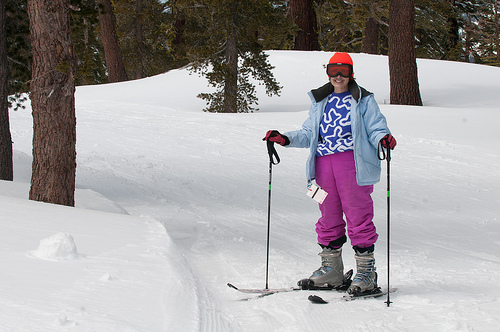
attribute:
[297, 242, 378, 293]
boots — tall, grey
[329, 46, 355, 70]
cap — orange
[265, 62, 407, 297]
woman — standing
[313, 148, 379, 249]
pants — purple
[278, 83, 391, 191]
jacket — blue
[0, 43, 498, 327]
snow — white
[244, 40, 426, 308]
woman — skiing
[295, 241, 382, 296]
boots — gray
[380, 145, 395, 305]
pole —  black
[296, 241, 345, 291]
ski boot — gray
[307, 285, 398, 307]
ski — black, grey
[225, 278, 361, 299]
ski — grey, black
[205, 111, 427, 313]
poles — long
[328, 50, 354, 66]
hat — bright orange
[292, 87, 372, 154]
sweater — blue, white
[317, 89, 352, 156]
sweater — dark blue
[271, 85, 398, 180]
jacket —  light blue, black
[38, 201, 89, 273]
snow — powdery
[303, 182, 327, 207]
tag — black, white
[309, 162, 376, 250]
pants — bright pink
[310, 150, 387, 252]
pants —  purple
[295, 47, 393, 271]
skier — skiing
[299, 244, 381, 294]
ski shoes —  grey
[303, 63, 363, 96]
goggles — black, red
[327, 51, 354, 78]
hat — orange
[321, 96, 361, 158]
shirt — blue, white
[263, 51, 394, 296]
woman — smiling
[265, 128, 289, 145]
glove — red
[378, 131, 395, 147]
glove — red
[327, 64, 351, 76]
goggles — big, black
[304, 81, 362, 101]
collar — light blue, black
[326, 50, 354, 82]
hat — orange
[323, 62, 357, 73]
goggles — clear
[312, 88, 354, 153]
shirt — blue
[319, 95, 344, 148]
lines — white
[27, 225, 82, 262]
snow — white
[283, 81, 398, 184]
winter coat. — light blue